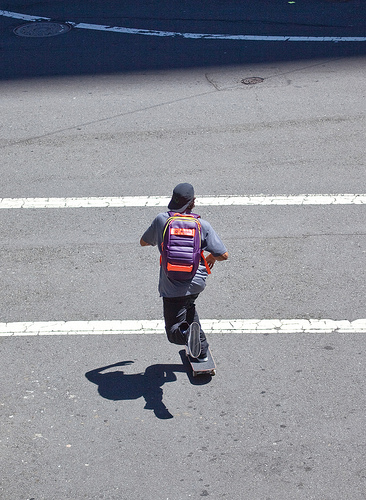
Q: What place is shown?
A: It is a street.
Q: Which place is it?
A: It is a street.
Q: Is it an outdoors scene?
A: Yes, it is outdoors.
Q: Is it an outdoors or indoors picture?
A: It is outdoors.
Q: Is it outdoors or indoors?
A: It is outdoors.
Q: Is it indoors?
A: No, it is outdoors.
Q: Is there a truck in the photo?
A: No, there are no trucks.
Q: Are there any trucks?
A: No, there are no trucks.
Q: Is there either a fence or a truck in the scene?
A: No, there are no trucks or fences.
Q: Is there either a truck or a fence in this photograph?
A: No, there are no trucks or fences.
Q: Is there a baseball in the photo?
A: No, there are no baseballs.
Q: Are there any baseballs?
A: No, there are no baseballs.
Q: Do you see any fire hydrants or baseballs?
A: No, there are no baseballs or fire hydrants.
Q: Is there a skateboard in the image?
A: Yes, there is a skateboard.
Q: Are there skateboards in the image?
A: Yes, there is a skateboard.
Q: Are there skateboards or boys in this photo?
A: Yes, there is a skateboard.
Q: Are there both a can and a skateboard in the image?
A: No, there is a skateboard but no cans.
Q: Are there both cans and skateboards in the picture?
A: No, there is a skateboard but no cans.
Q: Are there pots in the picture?
A: No, there are no pots.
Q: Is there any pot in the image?
A: No, there are no pots.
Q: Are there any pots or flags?
A: No, there are no pots or flags.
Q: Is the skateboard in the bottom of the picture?
A: Yes, the skateboard is in the bottom of the image.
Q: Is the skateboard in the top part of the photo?
A: No, the skateboard is in the bottom of the image.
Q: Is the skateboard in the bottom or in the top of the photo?
A: The skateboard is in the bottom of the image.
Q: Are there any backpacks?
A: Yes, there is a backpack.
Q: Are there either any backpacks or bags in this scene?
A: Yes, there is a backpack.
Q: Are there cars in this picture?
A: No, there are no cars.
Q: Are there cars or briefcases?
A: No, there are no cars or briefcases.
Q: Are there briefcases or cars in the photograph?
A: No, there are no cars or briefcases.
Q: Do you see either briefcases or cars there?
A: No, there are no cars or briefcases.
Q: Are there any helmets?
A: No, there are no helmets.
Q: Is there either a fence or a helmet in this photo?
A: No, there are no helmets or fences.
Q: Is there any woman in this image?
A: No, there are no women.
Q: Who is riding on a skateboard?
A: The boy is riding on a skateboard.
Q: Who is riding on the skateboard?
A: The boy is riding on a skateboard.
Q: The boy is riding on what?
A: The boy is riding on a skateboard.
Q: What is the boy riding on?
A: The boy is riding on a skateboard.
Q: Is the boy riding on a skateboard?
A: Yes, the boy is riding on a skateboard.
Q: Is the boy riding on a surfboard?
A: No, the boy is riding on a skateboard.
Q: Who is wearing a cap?
A: The boy is wearing a cap.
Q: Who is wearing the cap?
A: The boy is wearing a cap.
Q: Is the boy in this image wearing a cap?
A: Yes, the boy is wearing a cap.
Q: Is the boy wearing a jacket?
A: No, the boy is wearing a cap.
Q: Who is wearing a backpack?
A: The boy is wearing a backpack.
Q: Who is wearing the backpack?
A: The boy is wearing a backpack.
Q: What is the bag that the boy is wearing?
A: The bag is a backpack.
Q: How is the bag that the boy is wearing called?
A: The bag is a backpack.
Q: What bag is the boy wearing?
A: The boy is wearing a backpack.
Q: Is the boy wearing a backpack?
A: Yes, the boy is wearing a backpack.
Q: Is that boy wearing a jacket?
A: No, the boy is wearing a backpack.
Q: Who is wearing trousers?
A: The boy is wearing trousers.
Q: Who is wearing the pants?
A: The boy is wearing trousers.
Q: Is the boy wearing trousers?
A: Yes, the boy is wearing trousers.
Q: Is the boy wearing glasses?
A: No, the boy is wearing trousers.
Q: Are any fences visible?
A: No, there are no fences.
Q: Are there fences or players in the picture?
A: No, there are no fences or players.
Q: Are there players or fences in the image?
A: No, there are no fences or players.